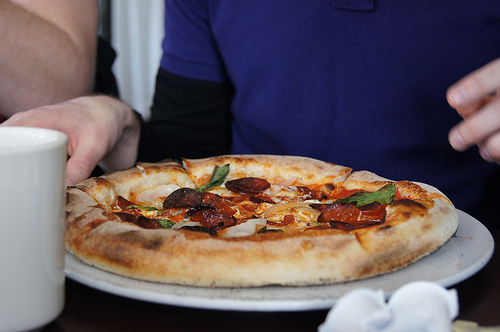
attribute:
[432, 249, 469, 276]
plate — round, white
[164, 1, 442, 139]
shirt — blue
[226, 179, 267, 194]
pepperoni — topping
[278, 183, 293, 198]
cheese — topping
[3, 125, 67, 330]
cup — white